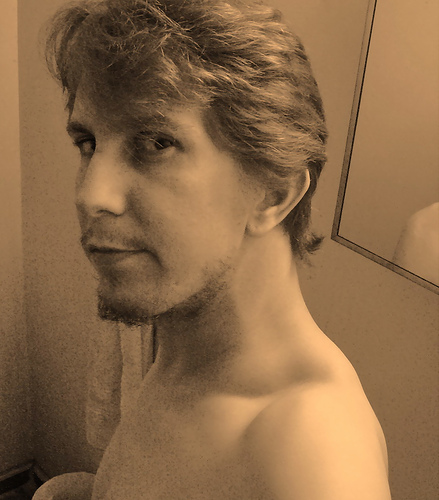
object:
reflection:
[391, 198, 439, 290]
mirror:
[331, 0, 439, 299]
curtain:
[82, 314, 167, 456]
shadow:
[97, 264, 246, 417]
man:
[33, 0, 397, 500]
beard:
[91, 264, 232, 333]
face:
[66, 52, 230, 325]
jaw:
[136, 190, 214, 285]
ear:
[245, 158, 314, 240]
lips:
[77, 225, 148, 250]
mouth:
[82, 237, 152, 267]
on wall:
[22, 0, 439, 500]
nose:
[75, 137, 125, 214]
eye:
[129, 124, 183, 163]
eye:
[68, 128, 98, 163]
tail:
[285, 184, 330, 274]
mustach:
[95, 296, 148, 329]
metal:
[328, 0, 439, 297]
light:
[203, 30, 307, 108]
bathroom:
[0, 0, 439, 497]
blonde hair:
[37, 0, 327, 266]